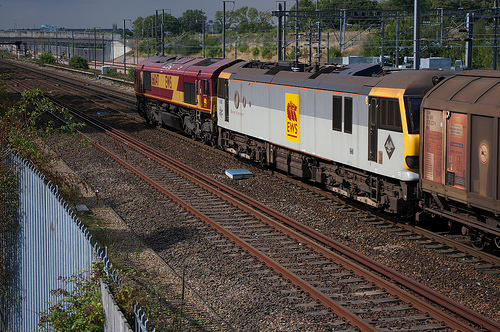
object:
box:
[225, 167, 253, 181]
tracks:
[1, 82, 381, 331]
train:
[135, 54, 500, 254]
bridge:
[1, 28, 135, 68]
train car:
[217, 59, 470, 222]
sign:
[284, 93, 300, 144]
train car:
[135, 54, 245, 146]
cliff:
[118, 25, 500, 73]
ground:
[0, 49, 500, 331]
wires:
[339, 24, 375, 46]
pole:
[414, 1, 420, 71]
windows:
[332, 95, 345, 133]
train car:
[415, 69, 500, 238]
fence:
[2, 150, 157, 331]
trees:
[69, 52, 92, 71]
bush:
[68, 56, 89, 70]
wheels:
[471, 227, 489, 250]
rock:
[280, 197, 287, 202]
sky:
[1, 0, 301, 34]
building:
[206, 20, 220, 35]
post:
[93, 27, 97, 68]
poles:
[464, 13, 472, 70]